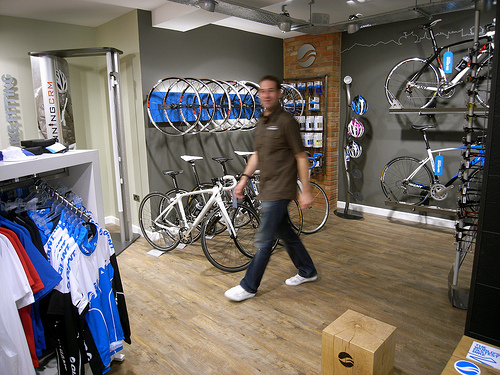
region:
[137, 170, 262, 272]
A white speed bike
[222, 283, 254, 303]
White athletic shoe on left foot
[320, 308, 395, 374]
A cardboard box on the floor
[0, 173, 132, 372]
A rack of shirts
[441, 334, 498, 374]
A box on the ground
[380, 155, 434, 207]
Back tire on a bike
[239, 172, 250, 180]
A wrist accessory being worn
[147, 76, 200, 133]
A tire hanging up on a rack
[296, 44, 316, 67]
A silver logo on a wall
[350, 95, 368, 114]
A blue bike helmet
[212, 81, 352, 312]
man walking in the room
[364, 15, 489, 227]
two bikes on the wall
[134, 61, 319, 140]
row of wheels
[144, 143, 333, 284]
bikes on display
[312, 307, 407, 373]
cardboard box sitting on the floor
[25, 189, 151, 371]
rack holding clothing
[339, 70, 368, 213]
helmets hanging up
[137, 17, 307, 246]
gray paint on the wall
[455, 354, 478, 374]
blue and white sticker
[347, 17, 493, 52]
white design on the top of the wall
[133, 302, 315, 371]
wooden floor for walking on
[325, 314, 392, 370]
small box on floor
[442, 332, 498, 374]
package on floor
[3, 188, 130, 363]
section of shirts for sale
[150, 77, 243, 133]
section of tires for sale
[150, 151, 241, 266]
section of bikes for sale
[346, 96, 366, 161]
section of helmets on display and for sale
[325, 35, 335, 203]
brick wall in corner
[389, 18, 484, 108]
bike on rack on wall on display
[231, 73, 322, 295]
man walking in store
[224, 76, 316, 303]
Man walking through a bike store.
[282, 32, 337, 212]
Brick wall with a metal logo.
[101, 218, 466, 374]
The floor is made of hardwood.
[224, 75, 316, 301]
Man in brown shirt and blue jean pants.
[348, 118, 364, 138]
A pink and white bike helmet.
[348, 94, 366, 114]
Blue and white bike helmet.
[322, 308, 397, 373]
Wooden block with a logo on it.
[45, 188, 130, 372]
Rack of blue and white bike suits.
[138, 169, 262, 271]
All white bicycle on the floor.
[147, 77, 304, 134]
Row of bicycle tires on the wall.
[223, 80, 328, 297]
a man walking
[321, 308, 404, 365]
a box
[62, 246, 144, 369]
shirts hanging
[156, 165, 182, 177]
a bike seat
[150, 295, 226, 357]
the wooden floor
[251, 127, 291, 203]
a brown shirt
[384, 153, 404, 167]
the tire on the bike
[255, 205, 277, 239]
the man is wearing jeans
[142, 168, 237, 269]
a bike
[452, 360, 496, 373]
a sticker on the box